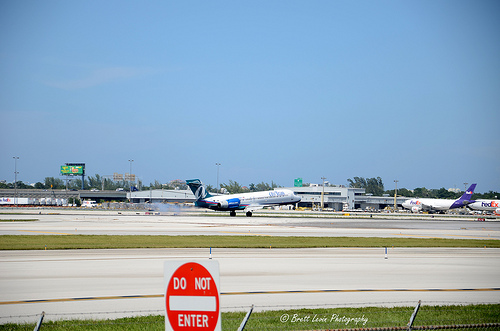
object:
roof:
[98, 204, 131, 212]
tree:
[31, 181, 42, 190]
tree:
[104, 178, 119, 189]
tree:
[86, 169, 103, 189]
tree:
[78, 176, 90, 190]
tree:
[0, 178, 37, 190]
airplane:
[185, 178, 301, 218]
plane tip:
[288, 189, 302, 203]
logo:
[479, 200, 499, 208]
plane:
[401, 183, 478, 215]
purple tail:
[448, 182, 480, 210]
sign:
[59, 162, 85, 177]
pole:
[81, 175, 85, 190]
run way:
[1, 246, 500, 321]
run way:
[0, 206, 498, 238]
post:
[14, 159, 17, 194]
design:
[184, 178, 213, 201]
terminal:
[271, 183, 365, 212]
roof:
[274, 184, 366, 194]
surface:
[0, 236, 500, 325]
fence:
[0, 301, 500, 331]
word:
[193, 277, 212, 291]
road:
[0, 217, 497, 327]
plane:
[185, 178, 302, 218]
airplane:
[400, 183, 477, 215]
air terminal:
[0, 0, 499, 331]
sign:
[164, 261, 221, 331]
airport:
[0, 178, 500, 331]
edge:
[320, 245, 353, 249]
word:
[172, 276, 187, 290]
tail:
[185, 178, 213, 209]